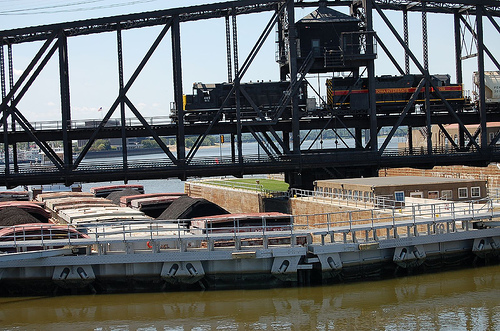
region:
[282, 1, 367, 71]
a hut on a bridge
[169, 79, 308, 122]
the lead engine of the train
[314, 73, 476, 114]
the second engine of the train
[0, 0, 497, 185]
a railroad bridge across a river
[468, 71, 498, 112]
the first train car behind the engines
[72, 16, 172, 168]
a truss to support the bridge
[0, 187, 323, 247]
cargo behind a gate in the river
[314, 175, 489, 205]
a small building with a flat roof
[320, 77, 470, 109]
an engine with an orange stripe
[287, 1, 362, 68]
small building with a pointed roof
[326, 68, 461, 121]
ths is a train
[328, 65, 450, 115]
the train is black in color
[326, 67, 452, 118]
the train is on the bridge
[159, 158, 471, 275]
this is a ferry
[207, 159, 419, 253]
the ferry is big in size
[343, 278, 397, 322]
the water is calm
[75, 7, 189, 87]
this is a bridge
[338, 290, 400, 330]
the water is brown in color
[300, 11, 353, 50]
this is a house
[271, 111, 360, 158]
the bridge is metallic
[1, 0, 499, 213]
a bridge over a body of water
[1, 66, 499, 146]
trucks running over a bridge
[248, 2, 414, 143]
a house in a bridge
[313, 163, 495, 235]
a building near a bridge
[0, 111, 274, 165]
buildings behind a bridge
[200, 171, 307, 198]
a field of green grass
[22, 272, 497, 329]
water is green and looks dirty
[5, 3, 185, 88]
wires over a bridge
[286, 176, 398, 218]
rails in font a building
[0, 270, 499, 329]
reflections on the water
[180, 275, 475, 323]
the water is calm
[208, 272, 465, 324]
the water is brown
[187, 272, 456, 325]
the water is murky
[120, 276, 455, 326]
the water is reflecting objects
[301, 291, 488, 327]
the sky is reflecting in the water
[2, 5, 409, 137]
the sky is overcast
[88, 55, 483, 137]
a train above the water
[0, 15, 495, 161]
a train on the bridge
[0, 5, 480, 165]
the bridge is black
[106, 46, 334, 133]
the front car is black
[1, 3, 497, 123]
blue of daytime sky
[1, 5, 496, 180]
frame of train bridge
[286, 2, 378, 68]
bulding on train bridge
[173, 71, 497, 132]
train traveling on bridge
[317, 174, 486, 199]
flat roof of building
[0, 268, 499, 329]
surface of calm water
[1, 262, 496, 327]
water with brown and green hue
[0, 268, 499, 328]
reflection on water surface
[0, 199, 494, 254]
railing on gray dock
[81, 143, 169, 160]
large ship on water